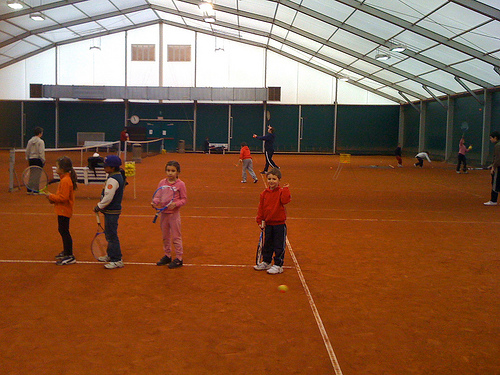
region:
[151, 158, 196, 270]
girl in a pink outfit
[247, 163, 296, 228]
boy wearing a red shirt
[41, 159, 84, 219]
girl wearing an orange sweater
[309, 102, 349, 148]
a wall of a building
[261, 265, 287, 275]
white shoes on a foot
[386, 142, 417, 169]
a child playing in the distance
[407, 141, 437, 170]
a child bending down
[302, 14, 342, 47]
rafters of a building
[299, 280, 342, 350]
white line on the ground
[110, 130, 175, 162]
a net with white trim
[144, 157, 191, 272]
girl in pink outfit holding racquet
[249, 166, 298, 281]
boy in red sweatshirt waving at photographer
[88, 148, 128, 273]
child in sport jacket waiting in line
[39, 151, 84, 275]
girl wearing orange sweatshirt waiting in line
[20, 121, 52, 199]
man walking away from camera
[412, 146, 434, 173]
person bending to pick something up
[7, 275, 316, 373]
orange colored tennis court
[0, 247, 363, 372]
white markings on tennis court floor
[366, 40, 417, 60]
silver lights hanging from clear ceiling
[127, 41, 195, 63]
signs on windows in background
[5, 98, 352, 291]
Children playing outdoor games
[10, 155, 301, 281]
Kids playing tennis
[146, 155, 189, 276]
Girl holding tennis racket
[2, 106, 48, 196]
Boy playing ping pong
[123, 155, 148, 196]
Basket full of tennis balls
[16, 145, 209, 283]
Children holding tennis rackets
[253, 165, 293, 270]
Boy wearing red sweater and blue sweatpants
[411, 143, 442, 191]
Child picking up tennis ball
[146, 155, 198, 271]
Girl wearing pink sweater and pants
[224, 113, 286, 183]
Children playing tennis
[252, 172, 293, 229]
The boy is wearing a coat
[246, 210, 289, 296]
The boy is wearing pants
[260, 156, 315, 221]
The boy is wearing black pants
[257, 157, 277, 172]
The boy has hair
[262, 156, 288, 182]
The boy has brown hair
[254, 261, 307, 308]
The boy has shoes on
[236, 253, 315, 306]
The boy has white shoes on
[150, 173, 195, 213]
The girl is wearing a shirt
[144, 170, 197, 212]
The girl is wearing a pink shirt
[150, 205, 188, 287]
The girl is wearing pants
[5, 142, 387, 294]
Kids playing in a gym.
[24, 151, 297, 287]
Kids holds tennis rackets.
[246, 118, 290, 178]
Adult wears blue outfit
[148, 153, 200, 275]
Girl wears pink cloths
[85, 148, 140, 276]
Kid has a blue cap on head.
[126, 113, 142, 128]
White clock on wall.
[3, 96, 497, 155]
Walls of gym are green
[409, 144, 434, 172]
Kid wears white top.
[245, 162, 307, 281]
Kid holds a tennis racket on right hand.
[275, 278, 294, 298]
Tennis ball on floor